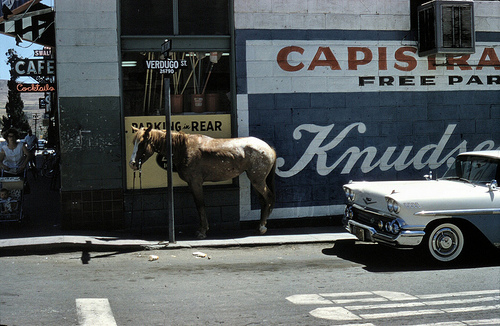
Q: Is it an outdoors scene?
A: Yes, it is outdoors.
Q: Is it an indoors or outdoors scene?
A: It is outdoors.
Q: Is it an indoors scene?
A: No, it is outdoors.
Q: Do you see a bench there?
A: No, there are no benches.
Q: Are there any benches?
A: No, there are no benches.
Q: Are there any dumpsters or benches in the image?
A: No, there are no benches or dumpsters.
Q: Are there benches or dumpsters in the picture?
A: No, there are no benches or dumpsters.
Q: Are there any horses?
A: Yes, there is a horse.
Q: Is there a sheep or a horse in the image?
A: Yes, there is a horse.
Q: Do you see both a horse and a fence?
A: No, there is a horse but no fences.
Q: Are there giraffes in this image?
A: No, there are no giraffes.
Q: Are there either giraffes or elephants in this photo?
A: No, there are no giraffes or elephants.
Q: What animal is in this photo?
A: The animal is a horse.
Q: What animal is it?
A: The animal is a horse.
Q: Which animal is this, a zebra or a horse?
A: This is a horse.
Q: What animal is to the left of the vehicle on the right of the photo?
A: The animal is a horse.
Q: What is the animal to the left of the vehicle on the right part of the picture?
A: The animal is a horse.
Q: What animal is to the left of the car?
A: The animal is a horse.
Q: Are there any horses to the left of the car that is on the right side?
A: Yes, there is a horse to the left of the car.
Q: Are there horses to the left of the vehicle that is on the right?
A: Yes, there is a horse to the left of the car.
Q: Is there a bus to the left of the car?
A: No, there is a horse to the left of the car.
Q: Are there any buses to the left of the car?
A: No, there is a horse to the left of the car.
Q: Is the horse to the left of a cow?
A: No, the horse is to the left of the car.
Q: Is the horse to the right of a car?
A: No, the horse is to the left of a car.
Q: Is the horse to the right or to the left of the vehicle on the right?
A: The horse is to the left of the car.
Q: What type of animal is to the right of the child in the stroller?
A: The animal is a horse.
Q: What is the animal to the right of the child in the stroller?
A: The animal is a horse.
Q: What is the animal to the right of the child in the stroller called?
A: The animal is a horse.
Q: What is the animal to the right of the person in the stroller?
A: The animal is a horse.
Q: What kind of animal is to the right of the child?
A: The animal is a horse.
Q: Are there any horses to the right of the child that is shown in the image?
A: Yes, there is a horse to the right of the child.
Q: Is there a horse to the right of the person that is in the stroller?
A: Yes, there is a horse to the right of the child.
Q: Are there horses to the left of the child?
A: No, the horse is to the right of the child.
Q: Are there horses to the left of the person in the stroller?
A: No, the horse is to the right of the child.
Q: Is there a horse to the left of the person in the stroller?
A: No, the horse is to the right of the child.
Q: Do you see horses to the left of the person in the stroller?
A: No, the horse is to the right of the child.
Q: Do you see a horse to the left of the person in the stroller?
A: No, the horse is to the right of the child.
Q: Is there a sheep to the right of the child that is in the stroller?
A: No, there is a horse to the right of the kid.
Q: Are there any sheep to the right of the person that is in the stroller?
A: No, there is a horse to the right of the kid.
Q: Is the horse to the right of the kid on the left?
A: Yes, the horse is to the right of the child.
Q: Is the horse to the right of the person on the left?
A: Yes, the horse is to the right of the child.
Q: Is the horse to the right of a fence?
A: No, the horse is to the right of the child.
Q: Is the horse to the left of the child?
A: No, the horse is to the right of the child.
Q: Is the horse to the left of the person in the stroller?
A: No, the horse is to the right of the child.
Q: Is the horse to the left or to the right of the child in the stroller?
A: The horse is to the right of the kid.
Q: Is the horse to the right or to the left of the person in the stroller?
A: The horse is to the right of the kid.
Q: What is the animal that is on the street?
A: The animal is a horse.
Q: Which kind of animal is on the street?
A: The animal is a horse.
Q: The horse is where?
A: The horse is on the street.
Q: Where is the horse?
A: The horse is on the street.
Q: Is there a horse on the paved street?
A: Yes, there is a horse on the street.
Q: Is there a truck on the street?
A: No, there is a horse on the street.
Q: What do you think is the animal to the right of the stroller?
A: The animal is a horse.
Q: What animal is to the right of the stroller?
A: The animal is a horse.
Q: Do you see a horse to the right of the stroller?
A: Yes, there is a horse to the right of the stroller.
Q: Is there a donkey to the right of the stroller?
A: No, there is a horse to the right of the stroller.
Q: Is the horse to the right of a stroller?
A: Yes, the horse is to the right of a stroller.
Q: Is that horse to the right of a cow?
A: No, the horse is to the right of a stroller.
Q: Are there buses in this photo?
A: No, there are no buses.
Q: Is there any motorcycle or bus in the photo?
A: No, there are no buses or motorcycles.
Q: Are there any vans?
A: No, there are no vans.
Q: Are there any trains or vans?
A: No, there are no vans or trains.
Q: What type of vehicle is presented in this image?
A: The vehicle is a car.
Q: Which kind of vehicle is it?
A: The vehicle is a car.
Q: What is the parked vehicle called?
A: The vehicle is a car.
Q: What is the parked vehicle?
A: The vehicle is a car.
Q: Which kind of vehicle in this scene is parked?
A: The vehicle is a car.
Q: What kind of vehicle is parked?
A: The vehicle is a car.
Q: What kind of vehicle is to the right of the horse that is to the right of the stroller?
A: The vehicle is a car.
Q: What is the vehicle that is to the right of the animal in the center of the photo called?
A: The vehicle is a car.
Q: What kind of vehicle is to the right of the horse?
A: The vehicle is a car.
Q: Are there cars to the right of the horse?
A: Yes, there is a car to the right of the horse.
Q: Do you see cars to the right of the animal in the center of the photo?
A: Yes, there is a car to the right of the horse.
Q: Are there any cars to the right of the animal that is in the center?
A: Yes, there is a car to the right of the horse.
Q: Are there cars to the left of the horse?
A: No, the car is to the right of the horse.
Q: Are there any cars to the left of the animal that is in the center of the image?
A: No, the car is to the right of the horse.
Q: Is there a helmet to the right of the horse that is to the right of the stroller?
A: No, there is a car to the right of the horse.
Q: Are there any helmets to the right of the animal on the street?
A: No, there is a car to the right of the horse.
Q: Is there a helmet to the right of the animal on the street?
A: No, there is a car to the right of the horse.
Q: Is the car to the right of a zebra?
A: No, the car is to the right of the horse.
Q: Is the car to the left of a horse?
A: No, the car is to the right of a horse.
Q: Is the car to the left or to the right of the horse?
A: The car is to the right of the horse.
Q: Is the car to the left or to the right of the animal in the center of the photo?
A: The car is to the right of the horse.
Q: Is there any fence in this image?
A: No, there are no fences.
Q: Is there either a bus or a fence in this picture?
A: No, there are no fences or buses.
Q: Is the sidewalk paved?
A: Yes, the sidewalk is paved.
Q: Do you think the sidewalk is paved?
A: Yes, the sidewalk is paved.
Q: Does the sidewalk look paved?
A: Yes, the sidewalk is paved.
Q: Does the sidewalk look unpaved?
A: No, the sidewalk is paved.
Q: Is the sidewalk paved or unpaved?
A: The sidewalk is paved.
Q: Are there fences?
A: No, there are no fences.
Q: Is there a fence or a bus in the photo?
A: No, there are no fences or buses.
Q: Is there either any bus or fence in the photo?
A: No, there are no fences or buses.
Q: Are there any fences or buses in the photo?
A: No, there are no fences or buses.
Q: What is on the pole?
A: The sign is on the pole.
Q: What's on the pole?
A: The sign is on the pole.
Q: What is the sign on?
A: The sign is on the pole.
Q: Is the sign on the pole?
A: Yes, the sign is on the pole.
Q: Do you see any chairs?
A: No, there are no chairs.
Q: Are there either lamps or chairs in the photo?
A: No, there are no chairs or lamps.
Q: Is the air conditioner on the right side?
A: Yes, the air conditioner is on the right of the image.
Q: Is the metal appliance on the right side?
A: Yes, the air conditioner is on the right of the image.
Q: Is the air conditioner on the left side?
A: No, the air conditioner is on the right of the image.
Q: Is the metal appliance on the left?
A: No, the air conditioner is on the right of the image.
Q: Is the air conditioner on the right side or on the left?
A: The air conditioner is on the right of the image.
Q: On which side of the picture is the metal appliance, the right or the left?
A: The air conditioner is on the right of the image.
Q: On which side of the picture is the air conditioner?
A: The air conditioner is on the right of the image.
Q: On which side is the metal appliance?
A: The air conditioner is on the right of the image.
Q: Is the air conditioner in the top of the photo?
A: Yes, the air conditioner is in the top of the image.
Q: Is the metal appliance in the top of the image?
A: Yes, the air conditioner is in the top of the image.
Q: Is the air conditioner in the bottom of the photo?
A: No, the air conditioner is in the top of the image.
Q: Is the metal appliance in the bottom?
A: No, the air conditioner is in the top of the image.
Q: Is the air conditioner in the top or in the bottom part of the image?
A: The air conditioner is in the top of the image.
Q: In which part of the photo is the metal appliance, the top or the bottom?
A: The air conditioner is in the top of the image.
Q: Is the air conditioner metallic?
A: Yes, the air conditioner is metallic.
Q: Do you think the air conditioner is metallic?
A: Yes, the air conditioner is metallic.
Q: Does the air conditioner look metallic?
A: Yes, the air conditioner is metallic.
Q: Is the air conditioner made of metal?
A: Yes, the air conditioner is made of metal.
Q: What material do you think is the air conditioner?
A: The air conditioner is made of metal.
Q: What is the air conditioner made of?
A: The air conditioner is made of metal.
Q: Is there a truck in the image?
A: No, there are no trucks.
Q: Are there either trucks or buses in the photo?
A: No, there are no trucks or buses.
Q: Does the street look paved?
A: Yes, the street is paved.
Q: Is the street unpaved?
A: No, the street is paved.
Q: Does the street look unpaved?
A: No, the street is paved.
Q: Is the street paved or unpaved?
A: The street is paved.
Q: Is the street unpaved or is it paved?
A: The street is paved.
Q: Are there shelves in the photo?
A: No, there are no shelves.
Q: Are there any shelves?
A: No, there are no shelves.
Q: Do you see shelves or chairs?
A: No, there are no shelves or chairs.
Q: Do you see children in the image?
A: Yes, there is a child.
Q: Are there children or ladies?
A: Yes, there is a child.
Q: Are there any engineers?
A: No, there are no engineers.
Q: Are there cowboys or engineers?
A: No, there are no engineers or cowboys.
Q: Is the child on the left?
A: Yes, the child is on the left of the image.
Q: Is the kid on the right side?
A: No, the kid is on the left of the image.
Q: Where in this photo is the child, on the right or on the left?
A: The child is on the left of the image.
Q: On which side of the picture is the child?
A: The child is on the left of the image.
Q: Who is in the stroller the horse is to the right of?
A: The child is in the stroller.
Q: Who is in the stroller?
A: The child is in the stroller.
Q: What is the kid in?
A: The kid is in the stroller.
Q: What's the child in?
A: The kid is in the stroller.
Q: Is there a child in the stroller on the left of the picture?
A: Yes, there is a child in the stroller.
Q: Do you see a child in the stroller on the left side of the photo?
A: Yes, there is a child in the stroller.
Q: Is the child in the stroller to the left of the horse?
A: Yes, the child is in the stroller.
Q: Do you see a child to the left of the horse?
A: Yes, there is a child to the left of the horse.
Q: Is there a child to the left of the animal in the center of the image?
A: Yes, there is a child to the left of the horse.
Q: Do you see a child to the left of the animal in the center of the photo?
A: Yes, there is a child to the left of the horse.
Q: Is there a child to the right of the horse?
A: No, the child is to the left of the horse.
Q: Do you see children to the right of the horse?
A: No, the child is to the left of the horse.